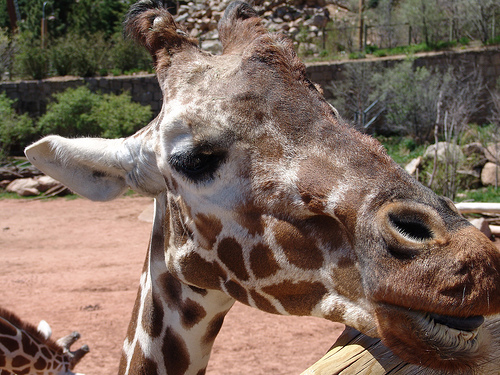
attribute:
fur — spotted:
[116, 194, 380, 371]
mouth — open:
[377, 287, 499, 351]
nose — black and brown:
[377, 197, 447, 263]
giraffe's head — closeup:
[24, 4, 499, 366]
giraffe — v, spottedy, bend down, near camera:
[23, 0, 498, 374]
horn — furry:
[124, 0, 215, 90]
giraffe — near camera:
[1, 308, 93, 373]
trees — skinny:
[325, 44, 486, 200]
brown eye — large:
[165, 140, 229, 190]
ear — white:
[14, 123, 160, 207]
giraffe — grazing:
[1, 301, 90, 373]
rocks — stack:
[399, 138, 481, 203]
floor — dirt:
[5, 201, 137, 316]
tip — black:
[137, 7, 167, 32]